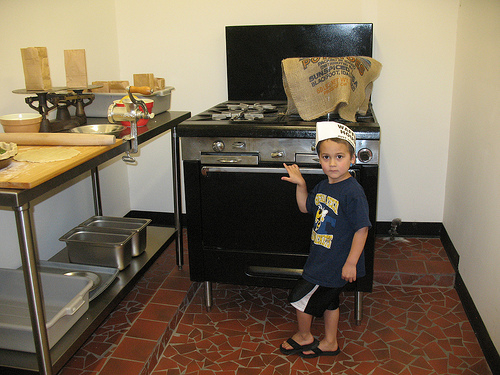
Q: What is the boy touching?
A: A stove.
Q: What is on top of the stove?
A: Burlap.